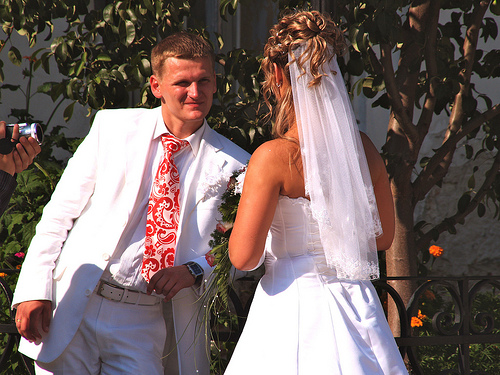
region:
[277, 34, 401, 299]
bride is wearing a veil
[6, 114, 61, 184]
man is holding a camera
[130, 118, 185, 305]
tie is white with red design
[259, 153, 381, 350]
woman is wearing a wedding dress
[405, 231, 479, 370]
flowers are bright orange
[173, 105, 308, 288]
man is leaning on a fence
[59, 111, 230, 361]
groom is wearing a white suit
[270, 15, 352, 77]
woman has her hair up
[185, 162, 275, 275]
bride is holding a bouquet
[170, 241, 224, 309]
groom is wearing a watch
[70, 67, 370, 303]
A bride and groom looking at each other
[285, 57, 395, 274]
The bride's veil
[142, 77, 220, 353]
Groom is wearing white with a patterned tie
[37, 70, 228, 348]
Groom is wearing a white suit and a red and white tie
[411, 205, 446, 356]
Orange flowers next to the tree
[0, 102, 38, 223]
A photographer taking pictures of the couple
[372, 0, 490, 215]
White wall behind the tree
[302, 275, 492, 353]
A black iron fence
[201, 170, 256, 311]
The bride's bouquet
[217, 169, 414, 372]
The bride's wedding gown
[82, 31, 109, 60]
leaves on the tree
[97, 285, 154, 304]
belt on man's waist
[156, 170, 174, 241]
design on man's tie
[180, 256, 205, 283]
watch on man's hands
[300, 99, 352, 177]
part of bride's veil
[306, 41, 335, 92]
hair on the bride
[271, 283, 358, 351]
back of wedding dress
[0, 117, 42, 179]
man holding the camera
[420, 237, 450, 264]
orange flower near tree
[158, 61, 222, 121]
face of the groom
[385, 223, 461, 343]
Orange flowers beside the tree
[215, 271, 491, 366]
A black iron fence behind the couple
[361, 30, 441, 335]
Large tree next to the fence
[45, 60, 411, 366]
Bride and groom looking at each other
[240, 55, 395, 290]
Bride's veil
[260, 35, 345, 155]
Bride's hair is half up and half down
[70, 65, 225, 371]
Groom is wearing all white with a red and white tie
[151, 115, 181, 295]
Groom wearing a patterned tie with red swirls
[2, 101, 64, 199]
A videographer filming the couple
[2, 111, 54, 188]
A camera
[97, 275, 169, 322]
A White Leather Belt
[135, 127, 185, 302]
Red and White Paisley Tie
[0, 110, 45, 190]
Hands Holding a Camera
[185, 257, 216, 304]
An Analog Wristwatch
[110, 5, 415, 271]
Young Bride and Her Groom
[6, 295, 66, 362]
Hand with Wedding Ring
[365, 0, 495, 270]
Tree in the Background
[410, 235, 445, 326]
Orange Flowers in the Shade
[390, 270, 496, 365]
A Black Cast Iron Fence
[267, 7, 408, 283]
A Simple White Bridal Veil